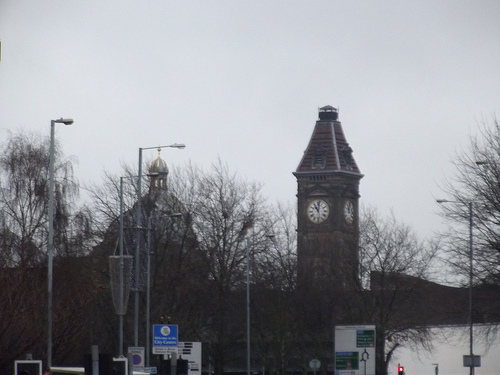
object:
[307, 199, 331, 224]
clock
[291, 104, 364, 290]
tower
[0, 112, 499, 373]
trees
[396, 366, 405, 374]
traffic light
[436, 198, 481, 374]
lamp post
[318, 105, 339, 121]
roof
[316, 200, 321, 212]
hands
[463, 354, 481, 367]
sign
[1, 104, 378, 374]
building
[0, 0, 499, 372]
sky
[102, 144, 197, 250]
dome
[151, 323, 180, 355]
sign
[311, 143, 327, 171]
window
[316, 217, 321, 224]
roman numerals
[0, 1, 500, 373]
city